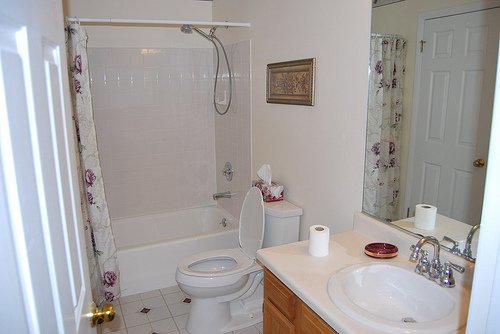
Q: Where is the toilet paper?
A: On counter.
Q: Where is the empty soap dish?
A: On counter top.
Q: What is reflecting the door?
A: The mirror.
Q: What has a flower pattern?
A: Shower curtain.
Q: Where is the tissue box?
A: On toilet tank.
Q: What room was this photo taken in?
A: The bathroom.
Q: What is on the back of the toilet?
A: A tissue box.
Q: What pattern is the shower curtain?
A: Floral.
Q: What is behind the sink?
A: A mirror.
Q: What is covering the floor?
A: Tile.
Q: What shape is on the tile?
A: A diamond.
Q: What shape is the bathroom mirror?
A: Rectangle.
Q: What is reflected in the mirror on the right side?
A: The door.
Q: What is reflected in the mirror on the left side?
A: Shower curtain.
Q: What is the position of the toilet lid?
A: Up.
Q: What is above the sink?
A: A mirror.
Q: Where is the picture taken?
A: In the bathroom.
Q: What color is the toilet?
A: White.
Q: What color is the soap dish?
A: Red.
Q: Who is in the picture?
A: There are no people in the picture.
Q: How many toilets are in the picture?
A: One.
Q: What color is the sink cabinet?
A: Brown.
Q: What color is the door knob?
A: Gold.